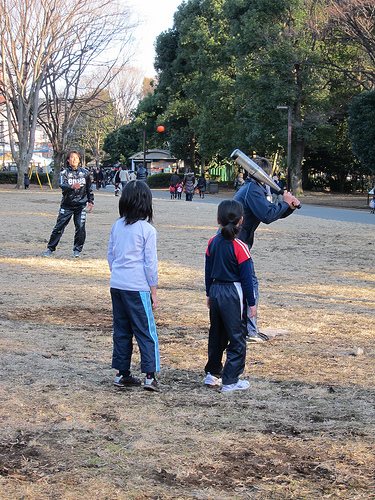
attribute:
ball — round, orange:
[154, 124, 164, 132]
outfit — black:
[36, 155, 100, 266]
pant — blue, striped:
[99, 282, 168, 395]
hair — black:
[214, 199, 247, 238]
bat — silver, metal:
[231, 148, 303, 210]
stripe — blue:
[139, 288, 160, 371]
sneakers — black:
[111, 371, 161, 395]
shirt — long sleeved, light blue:
[205, 233, 251, 282]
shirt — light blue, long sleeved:
[108, 216, 156, 292]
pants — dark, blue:
[201, 276, 244, 384]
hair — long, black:
[112, 175, 158, 219]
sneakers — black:
[107, 368, 170, 402]